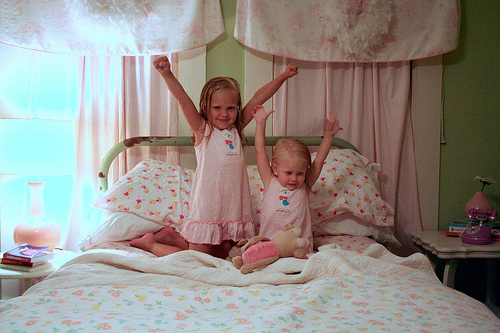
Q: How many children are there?
A: Two.